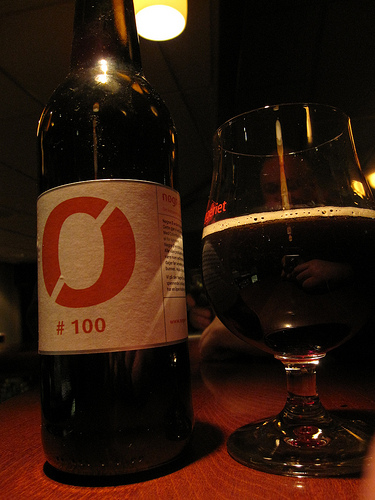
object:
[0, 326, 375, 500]
table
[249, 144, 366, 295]
person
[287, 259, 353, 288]
hand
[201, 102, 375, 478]
glass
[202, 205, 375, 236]
foam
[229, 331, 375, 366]
bottom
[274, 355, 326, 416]
stem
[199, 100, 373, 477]
wine glass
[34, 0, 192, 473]
bottle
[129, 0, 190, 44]
lampshade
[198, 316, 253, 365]
bad sentence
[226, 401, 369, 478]
base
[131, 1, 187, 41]
light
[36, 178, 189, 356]
number